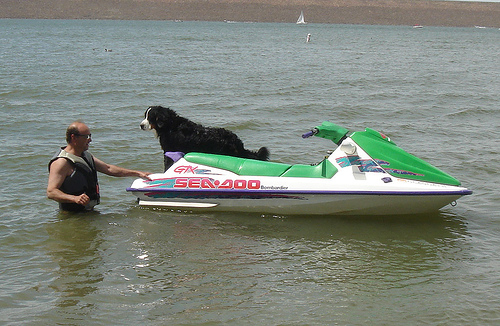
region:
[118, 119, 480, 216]
green and white jet ski in water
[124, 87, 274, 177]
large black and white dog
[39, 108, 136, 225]
man in waist deep water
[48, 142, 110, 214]
life jacket on man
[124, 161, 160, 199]
hand touching jet ski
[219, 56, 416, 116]
slightly choppy body of water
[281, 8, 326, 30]
sail boat on horizon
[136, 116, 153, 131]
white snout on dog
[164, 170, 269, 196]
logo on jet ski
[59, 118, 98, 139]
bald head of man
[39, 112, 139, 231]
Man is standing in water.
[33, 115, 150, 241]
The water is waist high on man.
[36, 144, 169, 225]
Man's hands are above water.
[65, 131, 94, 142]
Man is wearing glasses.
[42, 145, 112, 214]
Man is wearing life vest.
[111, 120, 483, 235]
Man is holding onto Sea-Doo.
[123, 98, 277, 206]
Dog is standing on Sea-Doo.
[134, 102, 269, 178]
Dog is black with white hair around his nose.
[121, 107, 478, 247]
The Sea-Doo is on the water.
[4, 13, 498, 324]
Water has a green tint to it.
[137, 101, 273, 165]
A black long haired dog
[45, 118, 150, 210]
A man standing in the water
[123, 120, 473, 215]
A green and white ski do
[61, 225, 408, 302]
Murky colored water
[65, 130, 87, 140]
glasses on man who is standing in water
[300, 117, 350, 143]
handle bars of ski do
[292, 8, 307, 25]
Little white sale boat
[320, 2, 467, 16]
brown earth in distance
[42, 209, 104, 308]
reflection of man in the water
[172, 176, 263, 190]
red logo on boat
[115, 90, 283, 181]
Dog is on top of a green jet ski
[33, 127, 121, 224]
Man is wearing a vest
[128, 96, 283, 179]
Dog's fur is black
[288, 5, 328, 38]
A boat is in the background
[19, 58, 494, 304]
The water is brown in color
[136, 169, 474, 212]
Jet ski has a purple line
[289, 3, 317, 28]
Sailboat in the background is white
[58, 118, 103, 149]
Man is wearing glasses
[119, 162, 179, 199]
Man is holding the back of the jet ski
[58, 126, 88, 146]
Man has dark colored hair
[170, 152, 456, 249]
the oat is green and white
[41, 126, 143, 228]
the vest is grey and black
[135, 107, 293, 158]
the dog is black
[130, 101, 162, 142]
the nose is white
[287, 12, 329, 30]
there is a boat in the distance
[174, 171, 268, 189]
the writing is red in color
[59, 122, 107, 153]
the man has glasses on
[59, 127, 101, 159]
the man is baldheaded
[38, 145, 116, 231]
the man is half in water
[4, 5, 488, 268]
it is daylight in the photot